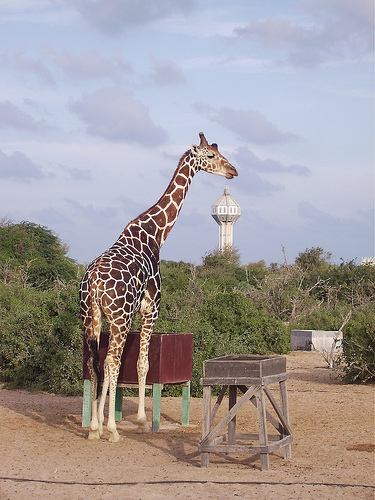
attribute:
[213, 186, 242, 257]
tower — white, far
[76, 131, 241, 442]
giraffe — standing, brown, white, tall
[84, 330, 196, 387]
box — brown, red, wooden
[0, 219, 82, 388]
tree — green, thick, large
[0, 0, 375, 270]
sky — blue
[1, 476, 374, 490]
shadow — rope, wire, dark, line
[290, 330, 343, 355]
structure — concrete, cement, square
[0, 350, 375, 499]
sand — dry